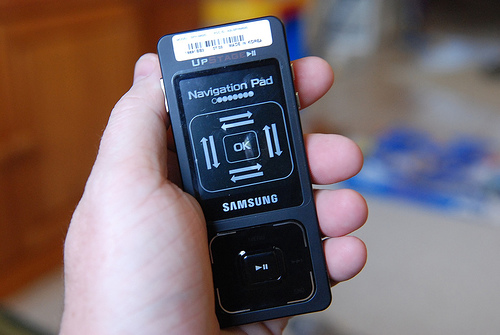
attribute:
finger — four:
[286, 38, 386, 293]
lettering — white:
[186, 72, 274, 99]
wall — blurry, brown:
[0, 2, 195, 277]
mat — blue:
[373, 117, 495, 198]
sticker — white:
[174, 19, 272, 64]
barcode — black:
[206, 37, 230, 48]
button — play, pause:
[239, 255, 292, 280]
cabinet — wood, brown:
[1, 3, 208, 307]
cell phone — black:
[155, 34, 291, 216]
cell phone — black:
[156, 12, 331, 329]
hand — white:
[47, 48, 332, 330]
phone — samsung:
[140, 12, 417, 329]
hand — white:
[59, 53, 369, 333]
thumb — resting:
[109, 35, 179, 157]